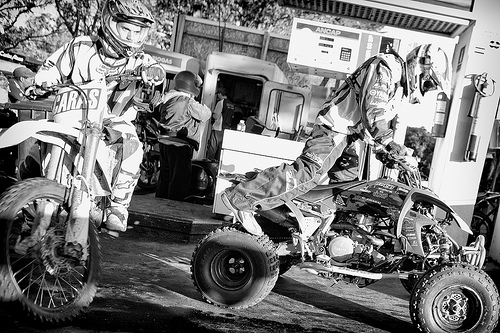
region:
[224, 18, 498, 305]
Man riding a quad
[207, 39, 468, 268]
The rider has one foot on the back tire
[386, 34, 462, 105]
The rider is wearing a helmet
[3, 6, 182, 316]
A man riding a dirtbike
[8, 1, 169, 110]
The rider is wearing a fox jersey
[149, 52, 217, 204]
A man standing with a helmet on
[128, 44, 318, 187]
A truck next to the side walk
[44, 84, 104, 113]
Black and white sticker on dirtbike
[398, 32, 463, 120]
Rider is wearing goggles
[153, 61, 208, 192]
Man wearing a large jacket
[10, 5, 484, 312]
two men on dirt bikes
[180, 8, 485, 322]
man standing on tire of dirt bike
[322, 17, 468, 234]
man with helmet and jacket on bike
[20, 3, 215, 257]
man sitting on motorcycle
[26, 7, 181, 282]
man sitting on dirt bike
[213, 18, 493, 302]
man mounting dirt bike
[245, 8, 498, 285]
man mounting motorcycle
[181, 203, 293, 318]
back right wheel of motorcycle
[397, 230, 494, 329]
front wheel of bike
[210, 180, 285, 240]
motorcyclist wearing white shoes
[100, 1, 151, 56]
The helmet the rider on the left is wearing.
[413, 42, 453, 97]
The helmet the rider on the right is wearing.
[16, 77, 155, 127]
The handle bars of the bike on the left.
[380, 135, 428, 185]
The handle bars of the 4 wheeler on the right.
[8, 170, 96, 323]
The front tire of the bike on the left.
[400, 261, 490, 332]
The front tire on the 4 wheeler.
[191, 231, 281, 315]
The back wheel of the 4 wheeler.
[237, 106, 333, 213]
The pants the rider on the right is wearing.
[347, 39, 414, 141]
The jacket the rider on the right is wearing.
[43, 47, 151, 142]
The jacket the rider on the left is wearing.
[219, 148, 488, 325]
ATV on the road.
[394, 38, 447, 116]
Helmet on the man's head.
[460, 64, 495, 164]
Fire extinguisher on the wall.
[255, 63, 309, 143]
Window in a door.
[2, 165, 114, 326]
Wire spokes in tire.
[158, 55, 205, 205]
Man is wearing jacket.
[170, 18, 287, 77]
Wooden fence behind truck.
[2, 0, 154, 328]
Man riding a motorcycle.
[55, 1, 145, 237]
Riding boots on man.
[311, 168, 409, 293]
Motor on ATV vehicle.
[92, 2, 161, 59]
helmet on man's head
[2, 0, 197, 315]
man riding motorcycle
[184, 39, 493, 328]
man standing on motorcycle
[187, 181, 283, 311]
foot on a tire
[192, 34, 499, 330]
man on motorcycle looking down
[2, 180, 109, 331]
front tire of motorcycle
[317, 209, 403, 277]
motor of motorcycle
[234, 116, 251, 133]
a bottle of water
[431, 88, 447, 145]
fire extinguisher with two labels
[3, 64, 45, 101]
man wearing baseball hat